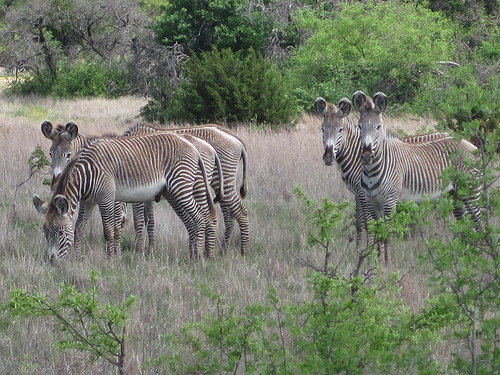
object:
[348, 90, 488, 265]
zebra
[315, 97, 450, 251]
zebra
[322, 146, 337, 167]
muzzle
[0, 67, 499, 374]
ground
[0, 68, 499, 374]
dry grass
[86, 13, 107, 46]
branches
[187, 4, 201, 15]
green leaves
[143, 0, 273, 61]
tree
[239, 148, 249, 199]
tail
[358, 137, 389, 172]
neck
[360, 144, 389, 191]
stripe pattern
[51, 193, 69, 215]
ear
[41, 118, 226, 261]
zebra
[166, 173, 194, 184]
stripe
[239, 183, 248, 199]
tip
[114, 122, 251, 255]
zebra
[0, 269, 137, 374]
bush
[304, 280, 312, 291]
leaf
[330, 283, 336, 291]
leaf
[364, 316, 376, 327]
leaf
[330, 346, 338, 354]
leaf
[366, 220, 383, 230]
leaf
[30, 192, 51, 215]
ear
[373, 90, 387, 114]
ear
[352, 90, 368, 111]
ear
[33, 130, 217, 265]
zebra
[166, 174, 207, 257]
legs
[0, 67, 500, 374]
field